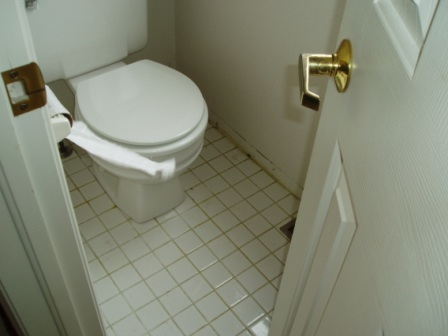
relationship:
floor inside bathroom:
[91, 182, 279, 330] [22, 0, 347, 334]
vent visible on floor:
[282, 220, 312, 243] [58, 118, 303, 336]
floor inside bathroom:
[58, 118, 303, 336] [22, 0, 347, 334]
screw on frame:
[18, 104, 27, 108] [3, 1, 111, 333]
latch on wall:
[0, 61, 47, 117] [8, 11, 88, 334]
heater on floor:
[277, 214, 299, 240] [58, 118, 303, 336]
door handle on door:
[295, 36, 351, 112] [307, 9, 432, 334]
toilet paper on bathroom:
[69, 125, 177, 176] [0, 0, 448, 336]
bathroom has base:
[0, 0, 448, 336] [120, 192, 188, 221]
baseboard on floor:
[213, 112, 302, 199] [203, 114, 306, 248]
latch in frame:
[0, 58, 49, 122] [3, 1, 111, 333]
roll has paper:
[42, 83, 74, 141] [71, 126, 168, 176]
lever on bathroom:
[24, 0, 39, 10] [0, 0, 448, 336]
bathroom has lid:
[0, 0, 448, 336] [72, 56, 207, 148]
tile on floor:
[225, 222, 255, 246] [58, 118, 303, 336]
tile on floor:
[213, 276, 249, 310] [58, 118, 303, 336]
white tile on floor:
[130, 251, 166, 279] [80, 204, 289, 323]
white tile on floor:
[183, 244, 220, 271] [80, 204, 289, 323]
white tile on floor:
[225, 176, 262, 199] [80, 204, 289, 323]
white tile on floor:
[211, 276, 250, 304] [80, 204, 289, 323]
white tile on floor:
[217, 221, 254, 250] [80, 204, 289, 323]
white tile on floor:
[177, 228, 201, 256] [76, 156, 282, 332]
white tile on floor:
[226, 251, 252, 270] [76, 156, 282, 332]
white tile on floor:
[183, 277, 209, 297] [76, 156, 282, 332]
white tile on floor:
[134, 253, 163, 275] [76, 156, 282, 332]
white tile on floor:
[215, 313, 243, 334] [76, 156, 282, 332]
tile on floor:
[178, 311, 202, 329] [76, 156, 282, 332]